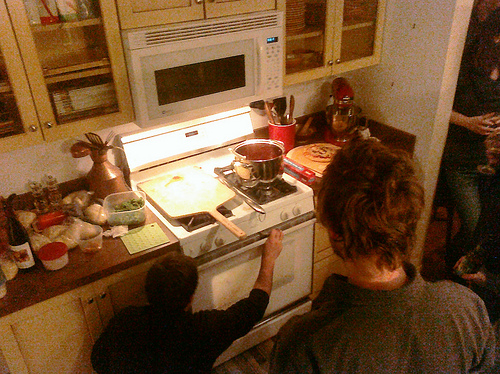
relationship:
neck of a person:
[345, 247, 407, 290] [271, 140, 496, 372]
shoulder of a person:
[272, 307, 343, 371] [271, 140, 496, 372]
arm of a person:
[216, 230, 283, 344] [92, 230, 281, 372]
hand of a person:
[470, 113, 492, 134] [452, 34, 489, 273]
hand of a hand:
[470, 113, 492, 134] [262, 225, 282, 256]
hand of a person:
[470, 113, 492, 134] [75, 228, 278, 371]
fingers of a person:
[470, 97, 498, 147] [442, 10, 497, 236]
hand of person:
[467, 112, 494, 135] [446, 39, 496, 203]